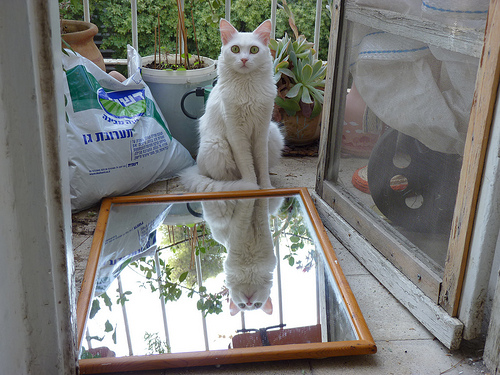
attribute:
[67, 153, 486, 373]
floor — part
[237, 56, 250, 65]
nose — pink 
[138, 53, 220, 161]
bucket — white 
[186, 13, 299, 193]
white cat — fluffy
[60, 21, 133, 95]
pot — empty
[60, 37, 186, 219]
bag — full, white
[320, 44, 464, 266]
reflection — part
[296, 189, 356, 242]
frame — brown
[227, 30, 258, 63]
eyes — round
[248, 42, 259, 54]
eye — green 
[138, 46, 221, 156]
bucket — White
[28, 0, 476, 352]
door — wooden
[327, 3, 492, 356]
door — wood, old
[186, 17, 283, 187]
cat — White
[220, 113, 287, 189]
cat legs — pair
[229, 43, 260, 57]
eyes — White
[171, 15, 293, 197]
cat — White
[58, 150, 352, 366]
mirror — brown 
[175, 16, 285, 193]
cat — White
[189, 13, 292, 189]
white cat — fluffy